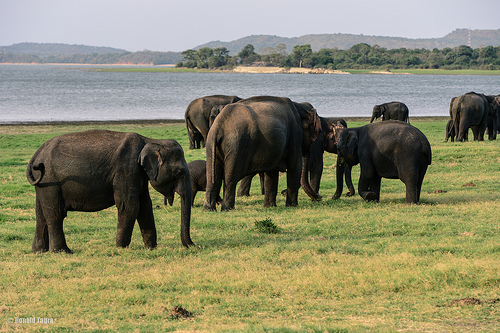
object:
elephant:
[23, 128, 203, 256]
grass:
[0, 115, 499, 332]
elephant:
[183, 95, 247, 151]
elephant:
[326, 118, 432, 204]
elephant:
[446, 90, 498, 141]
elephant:
[366, 101, 411, 125]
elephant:
[185, 158, 210, 209]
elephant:
[197, 95, 325, 214]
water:
[0, 63, 499, 124]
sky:
[0, 0, 499, 48]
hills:
[0, 24, 498, 64]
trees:
[174, 42, 499, 71]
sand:
[233, 64, 346, 73]